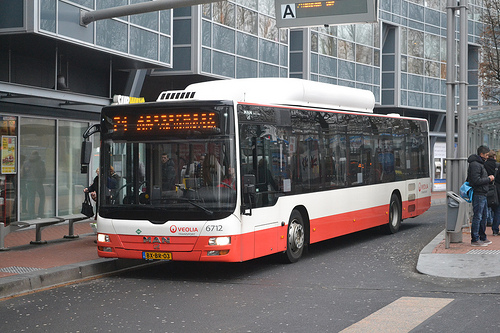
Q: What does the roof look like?
A: White.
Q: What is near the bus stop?
A: Buildings.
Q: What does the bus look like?
A: Red and white.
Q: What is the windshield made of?
A: Glass.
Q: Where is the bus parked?
A: Sidewalk.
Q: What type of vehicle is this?
A: Bus.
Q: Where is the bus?
A: On the street.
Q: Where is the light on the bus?
A: On the top.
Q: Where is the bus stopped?
A: On a street.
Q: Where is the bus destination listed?
A: Above the windshield.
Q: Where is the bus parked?
A: Near the bus stop.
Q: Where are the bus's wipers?
A: On the windshield.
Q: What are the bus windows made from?
A: Glass.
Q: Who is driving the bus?
A: The bus driver.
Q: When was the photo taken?
A: Daytime.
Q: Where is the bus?
A: Parked next to the sidewalk.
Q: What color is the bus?
A: Red and white.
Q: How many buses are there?
A: One.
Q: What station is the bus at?
A: A.